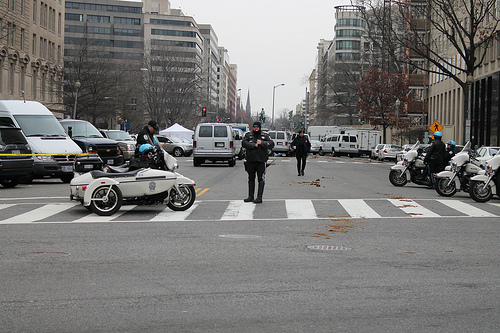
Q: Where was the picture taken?
A: It was taken at the street.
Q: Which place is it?
A: It is a street.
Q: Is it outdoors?
A: Yes, it is outdoors.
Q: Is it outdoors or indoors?
A: It is outdoors.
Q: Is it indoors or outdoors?
A: It is outdoors.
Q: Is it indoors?
A: No, it is outdoors.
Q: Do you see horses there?
A: No, there are no horses.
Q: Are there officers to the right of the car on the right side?
A: Yes, there is an officer to the right of the car.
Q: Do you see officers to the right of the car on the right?
A: Yes, there is an officer to the right of the car.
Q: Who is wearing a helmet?
A: The officer is wearing a helmet.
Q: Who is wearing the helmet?
A: The officer is wearing a helmet.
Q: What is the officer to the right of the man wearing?
A: The officer is wearing a helmet.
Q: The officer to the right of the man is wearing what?
A: The officer is wearing a helmet.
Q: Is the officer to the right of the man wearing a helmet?
A: Yes, the officer is wearing a helmet.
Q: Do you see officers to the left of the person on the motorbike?
A: Yes, there is an officer to the left of the person.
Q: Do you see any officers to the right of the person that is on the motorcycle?
A: No, the officer is to the left of the person.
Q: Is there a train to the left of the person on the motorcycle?
A: No, there is an officer to the left of the person.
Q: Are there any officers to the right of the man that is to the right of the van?
A: Yes, there is an officer to the right of the man.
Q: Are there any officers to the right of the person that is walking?
A: Yes, there is an officer to the right of the man.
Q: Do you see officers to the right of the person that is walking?
A: Yes, there is an officer to the right of the man.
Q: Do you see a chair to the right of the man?
A: No, there is an officer to the right of the man.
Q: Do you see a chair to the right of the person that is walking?
A: No, there is an officer to the right of the man.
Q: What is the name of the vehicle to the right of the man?
A: The vehicle is a car.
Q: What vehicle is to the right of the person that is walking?
A: The vehicle is a car.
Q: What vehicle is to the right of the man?
A: The vehicle is a car.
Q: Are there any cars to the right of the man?
A: Yes, there is a car to the right of the man.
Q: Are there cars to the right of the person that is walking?
A: Yes, there is a car to the right of the man.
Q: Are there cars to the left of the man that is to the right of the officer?
A: No, the car is to the right of the man.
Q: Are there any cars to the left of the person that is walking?
A: No, the car is to the right of the man.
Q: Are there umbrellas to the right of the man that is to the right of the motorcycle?
A: No, there is a car to the right of the man.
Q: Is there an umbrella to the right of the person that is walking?
A: No, there is a car to the right of the man.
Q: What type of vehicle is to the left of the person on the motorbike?
A: The vehicle is a car.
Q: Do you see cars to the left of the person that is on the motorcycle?
A: Yes, there is a car to the left of the person.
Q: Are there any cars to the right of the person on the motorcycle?
A: No, the car is to the left of the person.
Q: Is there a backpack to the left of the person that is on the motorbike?
A: No, there is a car to the left of the person.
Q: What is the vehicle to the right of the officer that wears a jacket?
A: The vehicle is a car.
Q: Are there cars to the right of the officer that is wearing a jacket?
A: Yes, there is a car to the right of the officer.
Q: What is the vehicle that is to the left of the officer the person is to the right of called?
A: The vehicle is a car.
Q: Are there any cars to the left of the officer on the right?
A: Yes, there is a car to the left of the officer.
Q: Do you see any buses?
A: No, there are no buses.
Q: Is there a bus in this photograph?
A: No, there are no buses.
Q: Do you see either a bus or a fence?
A: No, there are no buses or fences.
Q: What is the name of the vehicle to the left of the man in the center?
A: The vehicle is a van.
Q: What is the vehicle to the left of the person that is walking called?
A: The vehicle is a van.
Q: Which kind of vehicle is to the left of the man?
A: The vehicle is a van.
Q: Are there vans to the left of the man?
A: Yes, there is a van to the left of the man.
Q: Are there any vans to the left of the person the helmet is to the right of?
A: Yes, there is a van to the left of the man.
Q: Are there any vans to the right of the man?
A: No, the van is to the left of the man.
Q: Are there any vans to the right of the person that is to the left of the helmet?
A: No, the van is to the left of the man.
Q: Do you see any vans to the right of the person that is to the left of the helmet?
A: No, the van is to the left of the man.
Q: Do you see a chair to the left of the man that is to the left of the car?
A: No, there is a van to the left of the man.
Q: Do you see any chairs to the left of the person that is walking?
A: No, there is a van to the left of the man.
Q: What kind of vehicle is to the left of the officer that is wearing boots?
A: The vehicle is a van.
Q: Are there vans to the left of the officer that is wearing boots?
A: Yes, there is a van to the left of the officer.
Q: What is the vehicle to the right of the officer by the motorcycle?
A: The vehicle is a van.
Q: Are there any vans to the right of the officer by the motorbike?
A: Yes, there is a van to the right of the officer.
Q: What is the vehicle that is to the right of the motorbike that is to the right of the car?
A: The vehicle is a van.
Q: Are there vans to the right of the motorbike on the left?
A: Yes, there is a van to the right of the motorcycle.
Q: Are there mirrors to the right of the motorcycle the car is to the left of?
A: No, there is a van to the right of the motorbike.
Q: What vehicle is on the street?
A: The vehicle is a van.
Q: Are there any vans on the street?
A: Yes, there is a van on the street.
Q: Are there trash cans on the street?
A: No, there is a van on the street.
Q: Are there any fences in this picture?
A: No, there are no fences.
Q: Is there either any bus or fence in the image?
A: No, there are no fences or buses.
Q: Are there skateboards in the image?
A: No, there are no skateboards.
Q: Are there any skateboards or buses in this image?
A: No, there are no skateboards or buses.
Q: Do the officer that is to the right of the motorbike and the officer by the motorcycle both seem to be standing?
A: Yes, both the officer and the officer are standing.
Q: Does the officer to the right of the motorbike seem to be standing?
A: Yes, the officer is standing.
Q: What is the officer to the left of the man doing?
A: The officer is standing.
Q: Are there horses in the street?
A: No, there is an officer in the street.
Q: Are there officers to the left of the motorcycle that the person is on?
A: Yes, there is an officer to the left of the motorcycle.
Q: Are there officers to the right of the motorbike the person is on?
A: No, the officer is to the left of the motorcycle.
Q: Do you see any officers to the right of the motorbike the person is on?
A: No, the officer is to the left of the motorcycle.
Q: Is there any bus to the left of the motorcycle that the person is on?
A: No, there is an officer to the left of the motorbike.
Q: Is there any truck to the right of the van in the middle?
A: No, there is an officer to the right of the van.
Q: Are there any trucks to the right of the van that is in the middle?
A: No, there is an officer to the right of the van.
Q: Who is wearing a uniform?
A: The officer is wearing a uniform.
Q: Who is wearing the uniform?
A: The officer is wearing a uniform.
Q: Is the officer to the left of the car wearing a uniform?
A: Yes, the officer is wearing a uniform.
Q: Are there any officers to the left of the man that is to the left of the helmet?
A: Yes, there is an officer to the left of the man.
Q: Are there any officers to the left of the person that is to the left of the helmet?
A: Yes, there is an officer to the left of the man.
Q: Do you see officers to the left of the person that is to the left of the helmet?
A: Yes, there is an officer to the left of the man.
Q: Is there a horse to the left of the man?
A: No, there is an officer to the left of the man.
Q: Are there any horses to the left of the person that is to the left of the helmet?
A: No, there is an officer to the left of the man.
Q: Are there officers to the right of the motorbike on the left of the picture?
A: Yes, there is an officer to the right of the motorbike.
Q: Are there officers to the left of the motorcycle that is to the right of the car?
A: No, the officer is to the right of the motorcycle.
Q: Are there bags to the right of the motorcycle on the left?
A: No, there is an officer to the right of the motorbike.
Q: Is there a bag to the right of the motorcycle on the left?
A: No, there is an officer to the right of the motorbike.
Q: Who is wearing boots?
A: The officer is wearing boots.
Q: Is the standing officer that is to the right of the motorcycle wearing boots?
A: Yes, the officer is wearing boots.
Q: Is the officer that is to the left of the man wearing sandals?
A: No, the officer is wearing boots.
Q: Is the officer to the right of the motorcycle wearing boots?
A: Yes, the officer is wearing boots.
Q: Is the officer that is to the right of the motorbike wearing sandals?
A: No, the officer is wearing boots.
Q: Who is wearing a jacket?
A: The officer is wearing a jacket.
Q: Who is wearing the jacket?
A: The officer is wearing a jacket.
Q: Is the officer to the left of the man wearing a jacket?
A: Yes, the officer is wearing a jacket.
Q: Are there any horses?
A: No, there are no horses.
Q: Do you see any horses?
A: No, there are no horses.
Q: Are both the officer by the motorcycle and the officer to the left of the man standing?
A: Yes, both the officer and the officer are standing.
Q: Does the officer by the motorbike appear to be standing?
A: Yes, the officer is standing.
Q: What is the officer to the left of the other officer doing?
A: The officer is standing.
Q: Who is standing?
A: The officer is standing.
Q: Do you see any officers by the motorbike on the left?
A: Yes, there is an officer by the motorbike.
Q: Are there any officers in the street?
A: Yes, there is an officer in the street.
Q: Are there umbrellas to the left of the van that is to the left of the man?
A: No, there is an officer to the left of the van.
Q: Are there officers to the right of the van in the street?
A: Yes, there is an officer to the right of the van.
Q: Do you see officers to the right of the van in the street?
A: Yes, there is an officer to the right of the van.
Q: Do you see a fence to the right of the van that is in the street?
A: No, there is an officer to the right of the van.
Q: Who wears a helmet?
A: The officer wears a helmet.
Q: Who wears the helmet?
A: The officer wears a helmet.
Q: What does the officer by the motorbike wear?
A: The officer wears a helmet.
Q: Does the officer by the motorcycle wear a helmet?
A: Yes, the officer wears a helmet.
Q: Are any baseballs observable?
A: No, there are no baseballs.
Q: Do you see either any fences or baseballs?
A: No, there are no baseballs or fences.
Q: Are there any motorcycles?
A: Yes, there is a motorcycle.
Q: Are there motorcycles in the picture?
A: Yes, there is a motorcycle.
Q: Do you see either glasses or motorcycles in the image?
A: Yes, there is a motorcycle.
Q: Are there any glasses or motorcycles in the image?
A: Yes, there is a motorcycle.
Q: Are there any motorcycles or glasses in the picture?
A: Yes, there is a motorcycle.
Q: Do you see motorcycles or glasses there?
A: Yes, there is a motorcycle.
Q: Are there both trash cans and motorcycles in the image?
A: No, there is a motorcycle but no trash cans.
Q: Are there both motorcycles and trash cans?
A: No, there is a motorcycle but no trash cans.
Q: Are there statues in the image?
A: No, there are no statues.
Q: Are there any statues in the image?
A: No, there are no statues.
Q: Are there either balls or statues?
A: No, there are no statues or balls.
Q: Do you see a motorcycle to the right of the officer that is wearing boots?
A: Yes, there is a motorcycle to the right of the officer.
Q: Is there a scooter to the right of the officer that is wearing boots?
A: No, there is a motorcycle to the right of the officer.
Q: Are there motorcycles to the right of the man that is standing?
A: Yes, there is a motorcycle to the right of the man.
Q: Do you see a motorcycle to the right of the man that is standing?
A: Yes, there is a motorcycle to the right of the man.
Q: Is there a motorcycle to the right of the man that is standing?
A: Yes, there is a motorcycle to the right of the man.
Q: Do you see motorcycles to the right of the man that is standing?
A: Yes, there is a motorcycle to the right of the man.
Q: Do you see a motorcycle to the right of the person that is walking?
A: Yes, there is a motorcycle to the right of the man.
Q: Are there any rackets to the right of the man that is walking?
A: No, there is a motorcycle to the right of the man.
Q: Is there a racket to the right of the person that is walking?
A: No, there is a motorcycle to the right of the man.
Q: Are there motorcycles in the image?
A: Yes, there is a motorcycle.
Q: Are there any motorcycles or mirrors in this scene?
A: Yes, there is a motorcycle.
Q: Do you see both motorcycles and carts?
A: No, there is a motorcycle but no carts.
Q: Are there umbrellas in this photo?
A: No, there are no umbrellas.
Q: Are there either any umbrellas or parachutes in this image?
A: No, there are no umbrellas or parachutes.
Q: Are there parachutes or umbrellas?
A: No, there are no umbrellas or parachutes.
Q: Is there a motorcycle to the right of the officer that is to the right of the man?
A: Yes, there is a motorcycle to the right of the officer.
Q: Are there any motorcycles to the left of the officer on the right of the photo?
A: No, the motorcycle is to the right of the officer.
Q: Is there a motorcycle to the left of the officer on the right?
A: No, the motorcycle is to the right of the officer.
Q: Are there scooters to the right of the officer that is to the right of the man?
A: No, there is a motorcycle to the right of the officer.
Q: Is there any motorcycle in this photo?
A: Yes, there is a motorcycle.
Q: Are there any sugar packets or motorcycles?
A: Yes, there is a motorcycle.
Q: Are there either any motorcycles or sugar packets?
A: Yes, there is a motorcycle.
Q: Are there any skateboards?
A: No, there are no skateboards.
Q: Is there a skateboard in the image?
A: No, there are no skateboards.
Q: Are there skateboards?
A: No, there are no skateboards.